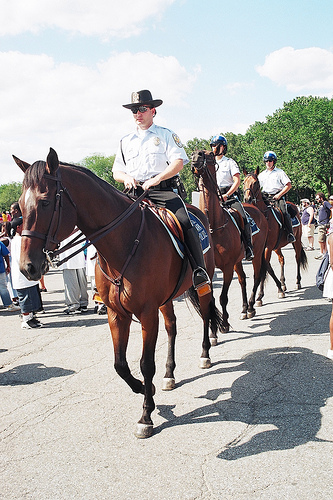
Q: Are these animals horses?
A: Yes, all the animals are horses.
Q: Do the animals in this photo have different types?
A: No, all the animals are horses.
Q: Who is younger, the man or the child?
A: The child is younger than the man.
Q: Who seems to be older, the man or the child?
A: The man is older than the child.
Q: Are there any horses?
A: Yes, there is a horse.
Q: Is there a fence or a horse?
A: Yes, there is a horse.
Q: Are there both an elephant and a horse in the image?
A: No, there is a horse but no elephants.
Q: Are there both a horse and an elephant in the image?
A: No, there is a horse but no elephants.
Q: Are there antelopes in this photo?
A: No, there are no antelopes.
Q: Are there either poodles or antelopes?
A: No, there are no antelopes or poodles.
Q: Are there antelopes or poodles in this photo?
A: No, there are no antelopes or poodles.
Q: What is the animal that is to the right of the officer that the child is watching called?
A: The animal is a horse.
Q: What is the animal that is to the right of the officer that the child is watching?
A: The animal is a horse.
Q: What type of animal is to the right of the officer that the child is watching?
A: The animal is a horse.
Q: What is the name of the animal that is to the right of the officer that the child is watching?
A: The animal is a horse.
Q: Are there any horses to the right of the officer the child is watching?
A: Yes, there is a horse to the right of the officer.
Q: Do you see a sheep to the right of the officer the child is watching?
A: No, there is a horse to the right of the officer.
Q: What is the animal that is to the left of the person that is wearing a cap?
A: The animal is a horse.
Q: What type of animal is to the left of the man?
A: The animal is a horse.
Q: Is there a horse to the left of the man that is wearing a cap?
A: Yes, there is a horse to the left of the man.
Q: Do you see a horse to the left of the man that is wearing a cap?
A: Yes, there is a horse to the left of the man.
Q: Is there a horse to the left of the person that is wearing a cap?
A: Yes, there is a horse to the left of the man.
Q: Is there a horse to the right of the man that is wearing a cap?
A: No, the horse is to the left of the man.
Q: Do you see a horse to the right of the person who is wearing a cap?
A: No, the horse is to the left of the man.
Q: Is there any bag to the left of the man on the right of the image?
A: No, there is a horse to the left of the man.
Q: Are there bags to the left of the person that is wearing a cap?
A: No, there is a horse to the left of the man.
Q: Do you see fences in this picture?
A: No, there are no fences.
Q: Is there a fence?
A: No, there are no fences.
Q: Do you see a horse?
A: Yes, there is a horse.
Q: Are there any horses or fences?
A: Yes, there is a horse.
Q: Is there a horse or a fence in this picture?
A: Yes, there is a horse.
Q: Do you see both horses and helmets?
A: Yes, there are both a horse and a helmet.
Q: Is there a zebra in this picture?
A: No, there are no zebras.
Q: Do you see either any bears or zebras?
A: No, there are no zebras or bears.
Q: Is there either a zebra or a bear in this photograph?
A: No, there are no zebras or bears.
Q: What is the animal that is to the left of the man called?
A: The animal is a horse.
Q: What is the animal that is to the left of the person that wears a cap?
A: The animal is a horse.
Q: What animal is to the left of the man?
A: The animal is a horse.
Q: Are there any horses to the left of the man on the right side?
A: Yes, there is a horse to the left of the man.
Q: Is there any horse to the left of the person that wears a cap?
A: Yes, there is a horse to the left of the man.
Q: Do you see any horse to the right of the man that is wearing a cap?
A: No, the horse is to the left of the man.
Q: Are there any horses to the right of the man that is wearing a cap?
A: No, the horse is to the left of the man.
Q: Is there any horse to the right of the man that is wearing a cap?
A: No, the horse is to the left of the man.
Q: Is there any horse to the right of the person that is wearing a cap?
A: No, the horse is to the left of the man.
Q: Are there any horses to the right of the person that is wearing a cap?
A: No, the horse is to the left of the man.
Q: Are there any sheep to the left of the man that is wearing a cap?
A: No, there is a horse to the left of the man.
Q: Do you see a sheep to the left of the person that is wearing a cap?
A: No, there is a horse to the left of the man.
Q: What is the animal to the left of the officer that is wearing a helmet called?
A: The animal is a horse.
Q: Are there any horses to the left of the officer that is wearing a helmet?
A: Yes, there is a horse to the left of the officer.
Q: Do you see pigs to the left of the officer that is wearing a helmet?
A: No, there is a horse to the left of the officer.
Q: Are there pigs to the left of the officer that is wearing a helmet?
A: No, there is a horse to the left of the officer.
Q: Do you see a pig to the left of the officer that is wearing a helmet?
A: No, there is a horse to the left of the officer.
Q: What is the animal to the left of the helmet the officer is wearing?
A: The animal is a horse.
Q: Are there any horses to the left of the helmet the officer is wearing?
A: Yes, there is a horse to the left of the helmet.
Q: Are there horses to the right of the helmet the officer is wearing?
A: No, the horse is to the left of the helmet.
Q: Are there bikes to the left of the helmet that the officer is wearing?
A: No, there is a horse to the left of the helmet.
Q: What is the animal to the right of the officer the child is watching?
A: The animal is a horse.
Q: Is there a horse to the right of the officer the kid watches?
A: Yes, there is a horse to the right of the officer.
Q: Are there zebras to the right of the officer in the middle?
A: No, there is a horse to the right of the officer.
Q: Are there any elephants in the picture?
A: No, there are no elephants.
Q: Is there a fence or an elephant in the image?
A: No, there are no elephants or fences.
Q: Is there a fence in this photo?
A: No, there are no fences.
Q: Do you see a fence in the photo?
A: No, there are no fences.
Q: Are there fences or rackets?
A: No, there are no fences or rackets.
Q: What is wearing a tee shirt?
A: The shorts are wearing a tee shirt.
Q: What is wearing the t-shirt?
A: The shorts are wearing a tee shirt.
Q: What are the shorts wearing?
A: The shorts are wearing a tshirt.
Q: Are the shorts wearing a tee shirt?
A: Yes, the shorts are wearing a tee shirt.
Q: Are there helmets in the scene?
A: Yes, there is a helmet.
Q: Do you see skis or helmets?
A: Yes, there is a helmet.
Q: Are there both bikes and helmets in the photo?
A: No, there is a helmet but no bikes.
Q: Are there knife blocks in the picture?
A: No, there are no knife blocks.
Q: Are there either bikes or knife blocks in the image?
A: No, there are no knife blocks or bikes.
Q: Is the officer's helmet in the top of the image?
A: Yes, the helmet is in the top of the image.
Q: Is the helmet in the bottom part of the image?
A: No, the helmet is in the top of the image.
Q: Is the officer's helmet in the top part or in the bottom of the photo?
A: The helmet is in the top of the image.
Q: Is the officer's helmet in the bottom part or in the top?
A: The helmet is in the top of the image.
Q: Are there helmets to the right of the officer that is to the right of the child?
A: Yes, there is a helmet to the right of the officer.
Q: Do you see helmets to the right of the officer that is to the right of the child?
A: Yes, there is a helmet to the right of the officer.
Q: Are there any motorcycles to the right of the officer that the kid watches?
A: No, there is a helmet to the right of the officer.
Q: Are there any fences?
A: No, there are no fences.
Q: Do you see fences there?
A: No, there are no fences.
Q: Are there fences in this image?
A: No, there are no fences.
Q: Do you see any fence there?
A: No, there are no fences.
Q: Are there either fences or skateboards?
A: No, there are no fences or skateboards.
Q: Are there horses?
A: Yes, there is a horse.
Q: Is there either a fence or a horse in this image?
A: Yes, there is a horse.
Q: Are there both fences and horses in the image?
A: No, there is a horse but no fences.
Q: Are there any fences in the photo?
A: No, there are no fences.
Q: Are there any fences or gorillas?
A: No, there are no fences or gorillas.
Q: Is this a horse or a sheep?
A: This is a horse.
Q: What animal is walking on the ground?
A: The horse is walking on the ground.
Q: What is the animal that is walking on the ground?
A: The animal is a horse.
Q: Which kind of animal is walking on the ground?
A: The animal is a horse.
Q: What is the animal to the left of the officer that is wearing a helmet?
A: The animal is a horse.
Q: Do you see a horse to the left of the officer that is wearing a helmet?
A: Yes, there is a horse to the left of the officer.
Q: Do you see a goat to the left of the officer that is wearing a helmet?
A: No, there is a horse to the left of the officer.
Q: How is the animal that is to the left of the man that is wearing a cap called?
A: The animal is a horse.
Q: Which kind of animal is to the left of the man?
A: The animal is a horse.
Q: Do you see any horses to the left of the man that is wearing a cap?
A: Yes, there is a horse to the left of the man.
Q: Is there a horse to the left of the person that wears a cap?
A: Yes, there is a horse to the left of the man.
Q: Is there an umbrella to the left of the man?
A: No, there is a horse to the left of the man.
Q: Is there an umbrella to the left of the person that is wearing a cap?
A: No, there is a horse to the left of the man.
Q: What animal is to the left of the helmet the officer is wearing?
A: The animal is a horse.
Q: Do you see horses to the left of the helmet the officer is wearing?
A: Yes, there is a horse to the left of the helmet.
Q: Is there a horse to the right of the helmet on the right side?
A: No, the horse is to the left of the helmet.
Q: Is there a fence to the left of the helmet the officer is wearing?
A: No, there is a horse to the left of the helmet.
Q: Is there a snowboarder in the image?
A: No, there are no snowboarders.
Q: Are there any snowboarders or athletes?
A: No, there are no snowboarders or athletes.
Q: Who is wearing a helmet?
A: The officer is wearing a helmet.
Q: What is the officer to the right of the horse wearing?
A: The officer is wearing a helmet.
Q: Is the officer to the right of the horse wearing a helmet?
A: Yes, the officer is wearing a helmet.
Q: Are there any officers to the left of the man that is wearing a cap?
A: Yes, there is an officer to the left of the man.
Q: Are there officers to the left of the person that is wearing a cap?
A: Yes, there is an officer to the left of the man.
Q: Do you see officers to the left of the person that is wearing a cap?
A: Yes, there is an officer to the left of the man.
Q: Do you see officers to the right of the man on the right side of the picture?
A: No, the officer is to the left of the man.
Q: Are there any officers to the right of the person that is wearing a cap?
A: No, the officer is to the left of the man.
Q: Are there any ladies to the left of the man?
A: No, there is an officer to the left of the man.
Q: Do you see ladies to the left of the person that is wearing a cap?
A: No, there is an officer to the left of the man.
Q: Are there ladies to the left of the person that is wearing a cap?
A: No, there is an officer to the left of the man.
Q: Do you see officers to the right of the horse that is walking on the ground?
A: Yes, there is an officer to the right of the horse.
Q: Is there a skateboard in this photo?
A: No, there are no skateboards.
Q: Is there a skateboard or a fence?
A: No, there are no skateboards or fences.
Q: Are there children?
A: Yes, there is a child.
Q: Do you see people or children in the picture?
A: Yes, there is a child.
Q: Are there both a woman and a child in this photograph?
A: No, there is a child but no women.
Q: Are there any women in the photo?
A: No, there are no women.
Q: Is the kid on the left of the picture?
A: Yes, the kid is on the left of the image.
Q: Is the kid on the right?
A: No, the kid is on the left of the image.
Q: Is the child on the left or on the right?
A: The child is on the left of the image.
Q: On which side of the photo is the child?
A: The child is on the left of the image.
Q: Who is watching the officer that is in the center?
A: The kid is watching the officer.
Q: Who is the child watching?
A: The child is watching the officer.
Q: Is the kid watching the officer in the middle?
A: Yes, the kid is watching the officer.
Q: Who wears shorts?
A: The kid wears shorts.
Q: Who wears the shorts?
A: The kid wears shorts.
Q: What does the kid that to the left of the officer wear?
A: The kid wears shorts.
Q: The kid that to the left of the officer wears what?
A: The kid wears shorts.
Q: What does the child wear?
A: The kid wears shorts.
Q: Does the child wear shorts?
A: Yes, the child wears shorts.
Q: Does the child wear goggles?
A: No, the child wears shorts.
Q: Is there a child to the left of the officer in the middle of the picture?
A: Yes, there is a child to the left of the officer.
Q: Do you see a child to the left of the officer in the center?
A: Yes, there is a child to the left of the officer.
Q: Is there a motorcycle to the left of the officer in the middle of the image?
A: No, there is a child to the left of the officer.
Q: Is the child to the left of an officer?
A: Yes, the child is to the left of an officer.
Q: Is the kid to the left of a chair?
A: No, the kid is to the left of an officer.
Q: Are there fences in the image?
A: No, there are no fences.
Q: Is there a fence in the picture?
A: No, there are no fences.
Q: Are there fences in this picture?
A: No, there are no fences.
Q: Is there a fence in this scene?
A: No, there are no fences.